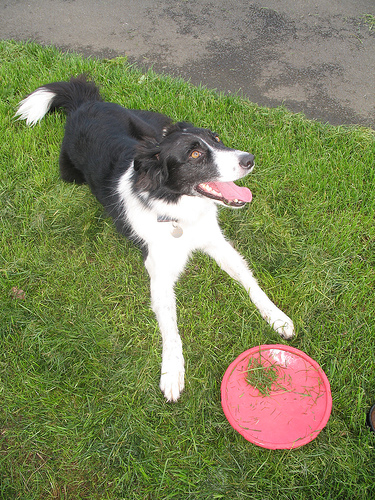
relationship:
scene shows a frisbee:
[4, 7, 369, 499] [223, 343, 331, 453]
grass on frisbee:
[249, 362, 276, 396] [223, 343, 331, 453]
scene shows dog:
[4, 7, 369, 499] [23, 77, 297, 403]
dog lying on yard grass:
[23, 77, 297, 403] [268, 110, 364, 223]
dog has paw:
[23, 77, 297, 403] [261, 306, 299, 341]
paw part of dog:
[261, 306, 299, 341] [23, 77, 297, 403]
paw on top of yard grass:
[261, 306, 299, 341] [268, 110, 364, 223]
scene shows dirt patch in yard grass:
[4, 7, 369, 499] [268, 110, 364, 223]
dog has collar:
[23, 77, 297, 403] [131, 185, 181, 226]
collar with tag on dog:
[131, 185, 181, 226] [23, 77, 297, 403]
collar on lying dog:
[131, 185, 181, 226] [23, 77, 297, 403]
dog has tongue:
[23, 77, 297, 403] [212, 182, 250, 203]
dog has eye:
[23, 77, 297, 403] [202, 157, 215, 167]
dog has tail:
[23, 77, 297, 403] [14, 81, 103, 126]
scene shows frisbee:
[4, 7, 369, 499] [223, 343, 331, 453]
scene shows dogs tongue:
[4, 7, 369, 499] [212, 182, 250, 203]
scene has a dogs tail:
[4, 7, 369, 499] [14, 81, 103, 126]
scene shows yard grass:
[4, 7, 369, 499] [268, 110, 364, 223]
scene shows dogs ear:
[4, 7, 369, 499] [133, 147, 166, 195]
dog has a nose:
[23, 77, 297, 403] [241, 157, 255, 169]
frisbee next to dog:
[223, 343, 331, 453] [23, 77, 297, 403]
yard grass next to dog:
[268, 110, 364, 223] [23, 77, 297, 403]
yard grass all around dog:
[268, 110, 364, 223] [23, 77, 297, 403]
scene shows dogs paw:
[4, 7, 369, 499] [261, 306, 299, 341]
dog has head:
[23, 77, 297, 403] [129, 127, 265, 209]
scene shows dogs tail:
[4, 7, 369, 499] [14, 81, 103, 126]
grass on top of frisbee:
[249, 362, 276, 396] [223, 343, 331, 453]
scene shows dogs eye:
[4, 7, 369, 499] [202, 157, 215, 167]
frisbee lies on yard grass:
[223, 343, 331, 453] [268, 110, 364, 223]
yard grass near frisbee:
[268, 110, 364, 223] [223, 343, 331, 453]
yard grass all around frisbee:
[268, 110, 364, 223] [223, 343, 331, 453]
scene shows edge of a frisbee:
[4, 7, 369, 499] [223, 343, 331, 453]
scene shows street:
[4, 7, 369, 499] [2, 7, 373, 123]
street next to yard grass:
[2, 7, 373, 123] [268, 110, 364, 223]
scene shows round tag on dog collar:
[4, 7, 369, 499] [131, 185, 181, 226]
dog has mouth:
[23, 77, 297, 403] [196, 179, 254, 210]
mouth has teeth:
[196, 179, 254, 210] [200, 191, 249, 206]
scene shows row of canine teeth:
[4, 7, 369, 499] [200, 191, 249, 206]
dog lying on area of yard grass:
[23, 77, 297, 403] [268, 110, 364, 223]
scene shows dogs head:
[4, 7, 369, 499] [129, 127, 265, 209]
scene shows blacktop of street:
[4, 7, 369, 499] [2, 7, 373, 123]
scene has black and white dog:
[4, 7, 369, 499] [23, 77, 297, 403]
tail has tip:
[14, 81, 103, 126] [13, 92, 56, 124]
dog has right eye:
[23, 77, 297, 403] [201, 154, 213, 166]